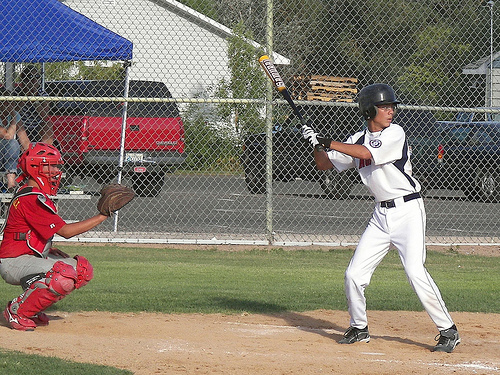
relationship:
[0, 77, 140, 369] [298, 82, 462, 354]
catcher behind baseball player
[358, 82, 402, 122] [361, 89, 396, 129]
helmet on head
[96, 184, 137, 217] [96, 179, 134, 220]
baseball glove on hand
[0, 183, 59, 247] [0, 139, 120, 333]
chest gear on catcher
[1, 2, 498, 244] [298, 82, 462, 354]
fence behind baseball player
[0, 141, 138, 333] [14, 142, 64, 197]
catcher in helmet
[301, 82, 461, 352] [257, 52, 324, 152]
baseball player holds bat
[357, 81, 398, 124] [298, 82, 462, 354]
helmet on baseball player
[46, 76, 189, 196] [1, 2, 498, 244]
red truck behind fence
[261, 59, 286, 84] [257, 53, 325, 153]
letters on bat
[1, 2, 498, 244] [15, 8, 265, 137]
fence in background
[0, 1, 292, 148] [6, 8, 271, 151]
house in background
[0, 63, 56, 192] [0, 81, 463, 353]
people watch baseball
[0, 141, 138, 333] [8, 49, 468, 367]
catcher plays baseball